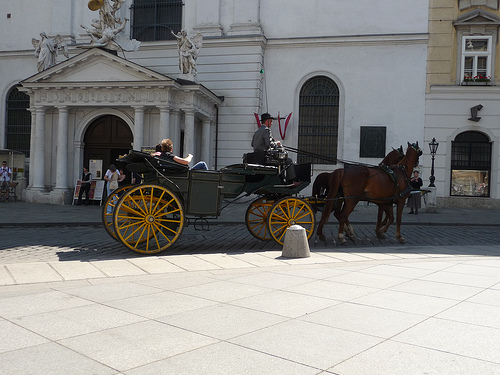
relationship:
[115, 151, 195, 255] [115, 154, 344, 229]
wheel on cart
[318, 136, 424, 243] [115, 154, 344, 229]
horse pulling cart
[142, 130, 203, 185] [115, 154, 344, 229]
men on cart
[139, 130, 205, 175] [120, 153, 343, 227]
people on carriage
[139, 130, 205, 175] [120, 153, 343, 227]
people in carriage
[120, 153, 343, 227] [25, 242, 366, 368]
carriage on street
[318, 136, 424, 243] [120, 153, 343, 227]
horse with carriage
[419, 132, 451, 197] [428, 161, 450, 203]
street light on stand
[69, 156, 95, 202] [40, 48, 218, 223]
people in front of building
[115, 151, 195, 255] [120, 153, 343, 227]
wheel on carriage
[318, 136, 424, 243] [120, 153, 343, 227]
horse pulling carriage